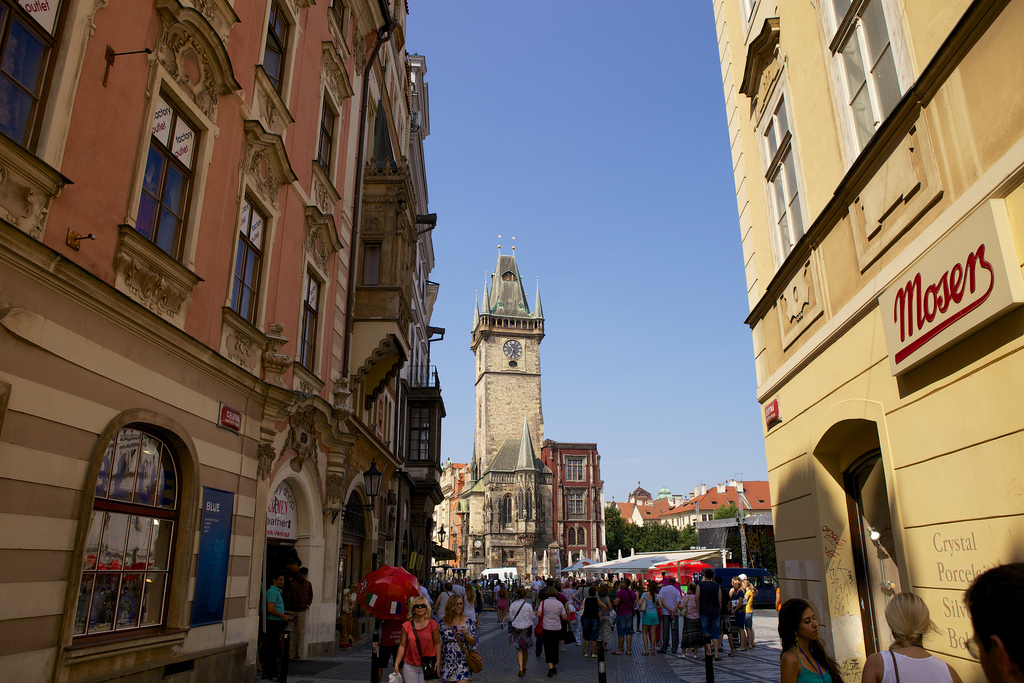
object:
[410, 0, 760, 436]
sky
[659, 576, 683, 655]
people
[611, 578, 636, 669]
people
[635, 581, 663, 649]
people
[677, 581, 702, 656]
people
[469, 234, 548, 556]
building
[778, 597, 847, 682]
woman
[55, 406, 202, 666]
window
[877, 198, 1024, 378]
sign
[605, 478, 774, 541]
building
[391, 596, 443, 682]
lady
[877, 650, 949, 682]
shirt